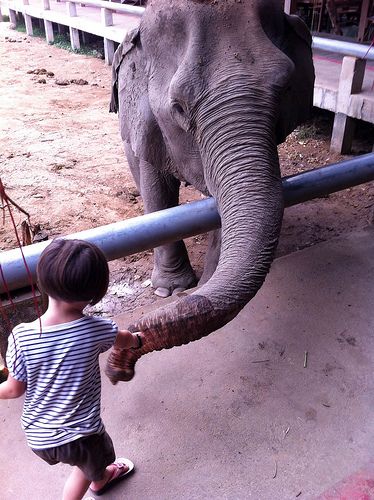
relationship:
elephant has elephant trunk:
[113, 1, 313, 385] [104, 89, 284, 388]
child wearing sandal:
[0, 236, 148, 499] [87, 454, 135, 496]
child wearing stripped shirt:
[0, 236, 148, 499] [1, 316, 157, 443]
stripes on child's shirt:
[7, 316, 120, 450] [10, 313, 119, 409]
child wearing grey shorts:
[0, 236, 148, 499] [5, 435, 160, 498]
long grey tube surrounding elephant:
[295, 11, 370, 67] [113, 1, 313, 385]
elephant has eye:
[113, 1, 313, 385] [170, 96, 190, 125]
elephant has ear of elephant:
[113, 1, 313, 385] [272, 8, 347, 144]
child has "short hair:
[0, 236, 148, 499] [23, 234, 121, 290]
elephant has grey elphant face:
[113, 1, 313, 385] [115, 1, 308, 135]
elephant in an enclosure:
[113, 1, 313, 385] [75, 1, 347, 355]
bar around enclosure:
[1, 151, 363, 297] [5, 0, 370, 294]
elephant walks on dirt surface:
[113, 1, 313, 385] [52, 121, 328, 327]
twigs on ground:
[254, 412, 307, 485] [94, 368, 362, 495]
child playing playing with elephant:
[26, 222, 155, 413] [113, 1, 313, 385]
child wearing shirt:
[7, 236, 145, 495] [5, 314, 117, 450]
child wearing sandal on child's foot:
[88, 453, 139, 499] [71, 448, 139, 498]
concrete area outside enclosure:
[98, 398, 317, 497] [10, 4, 362, 220]